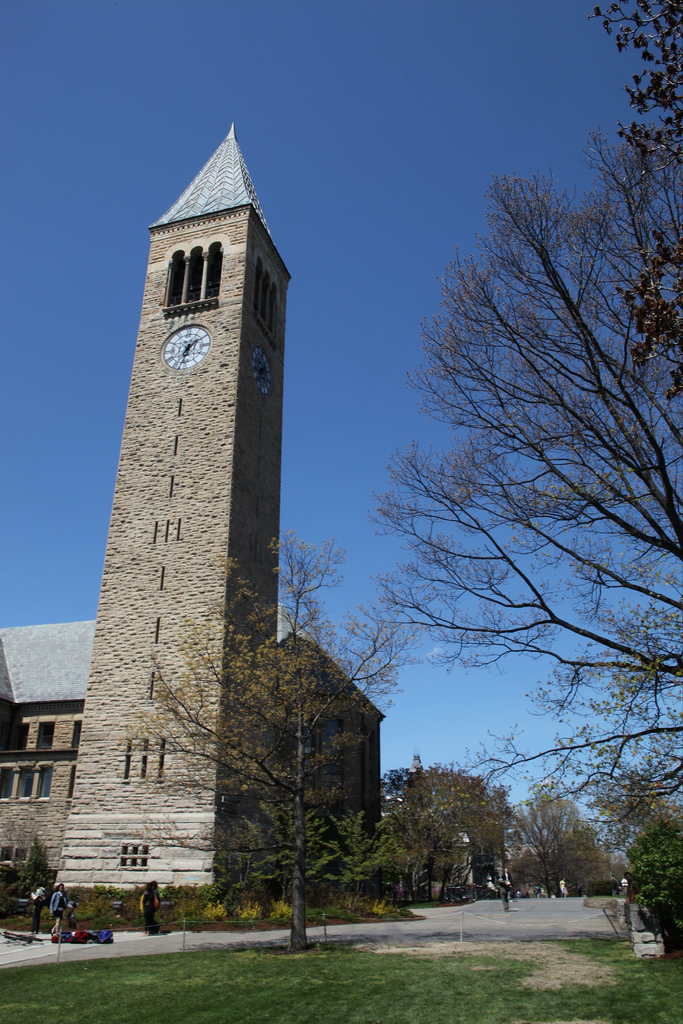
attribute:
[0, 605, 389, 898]
building — stone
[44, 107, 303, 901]
clocktower — tall, stone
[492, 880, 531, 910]
pants — green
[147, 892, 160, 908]
shirt — yellow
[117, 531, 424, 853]
leaves — yellow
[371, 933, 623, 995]
grass — patch, dead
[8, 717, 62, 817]
windows — set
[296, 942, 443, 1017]
lawn — green, grassy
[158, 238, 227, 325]
windows — set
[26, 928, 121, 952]
backpacks — red, blue